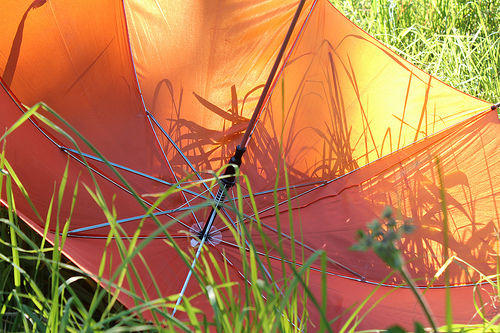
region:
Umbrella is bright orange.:
[2, 0, 497, 330]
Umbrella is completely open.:
[2, 1, 493, 327]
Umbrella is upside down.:
[2, 2, 497, 328]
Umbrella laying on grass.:
[5, 0, 497, 330]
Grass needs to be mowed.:
[0, 155, 421, 328]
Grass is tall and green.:
[2, 126, 357, 329]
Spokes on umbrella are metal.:
[5, 1, 497, 329]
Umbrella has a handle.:
[212, 0, 314, 187]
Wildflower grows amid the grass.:
[312, 193, 497, 329]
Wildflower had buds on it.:
[343, 201, 451, 331]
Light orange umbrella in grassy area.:
[13, 4, 468, 297]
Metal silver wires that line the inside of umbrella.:
[74, 101, 386, 319]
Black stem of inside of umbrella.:
[211, 1, 301, 198]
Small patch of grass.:
[351, 0, 498, 105]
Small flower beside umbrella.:
[348, 198, 419, 275]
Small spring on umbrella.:
[208, 180, 230, 204]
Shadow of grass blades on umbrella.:
[249, 16, 479, 188]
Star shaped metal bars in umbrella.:
[64, 101, 364, 308]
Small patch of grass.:
[11, 213, 76, 330]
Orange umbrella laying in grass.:
[20, 7, 459, 331]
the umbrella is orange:
[3, 2, 488, 331]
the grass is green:
[0, 4, 495, 331]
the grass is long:
[1, 0, 498, 324]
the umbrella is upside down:
[6, 0, 495, 331]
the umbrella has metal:
[50, 151, 332, 319]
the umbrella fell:
[3, 0, 498, 331]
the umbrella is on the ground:
[4, 0, 496, 331]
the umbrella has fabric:
[3, 1, 499, 331]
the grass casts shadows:
[1, 0, 495, 330]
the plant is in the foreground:
[351, 219, 435, 331]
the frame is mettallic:
[105, 147, 330, 255]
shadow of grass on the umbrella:
[296, 120, 400, 215]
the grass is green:
[408, 14, 488, 73]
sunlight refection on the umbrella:
[237, 45, 410, 115]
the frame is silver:
[124, 144, 329, 254]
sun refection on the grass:
[420, 24, 488, 63]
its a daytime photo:
[2, 4, 492, 316]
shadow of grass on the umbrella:
[190, 122, 419, 218]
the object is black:
[210, 148, 250, 184]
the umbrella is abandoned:
[3, 0, 498, 329]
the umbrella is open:
[0, 1, 499, 331]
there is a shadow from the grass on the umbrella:
[129, 22, 271, 186]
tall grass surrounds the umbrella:
[1, 0, 498, 332]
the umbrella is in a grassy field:
[0, 2, 495, 331]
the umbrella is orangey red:
[1, 2, 495, 331]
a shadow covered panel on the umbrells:
[190, 0, 499, 227]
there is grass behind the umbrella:
[330, 1, 499, 119]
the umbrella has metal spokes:
[56, 105, 367, 295]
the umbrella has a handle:
[198, 0, 311, 242]